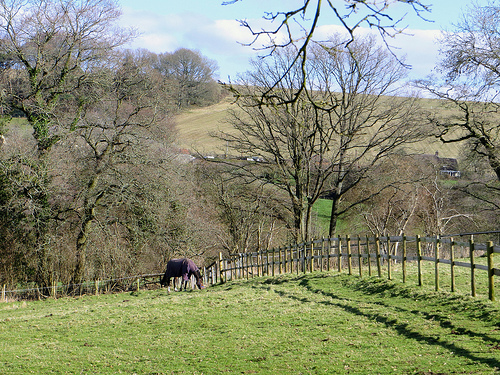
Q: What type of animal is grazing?
A: Horse.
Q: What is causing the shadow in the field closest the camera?
A: Fence.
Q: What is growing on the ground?
A: Grass.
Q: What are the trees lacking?
A: Leaves.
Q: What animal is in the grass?
A: Horse.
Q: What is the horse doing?
A: Eating.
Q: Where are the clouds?
A: In the sky.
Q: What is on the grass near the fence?
A: Shadow.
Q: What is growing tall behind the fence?
A: Trees.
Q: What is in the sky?
A: Clouds.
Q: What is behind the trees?
A: A house.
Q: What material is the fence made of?
A: Wood.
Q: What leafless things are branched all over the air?
A: Branches.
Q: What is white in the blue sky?
A: Clouds.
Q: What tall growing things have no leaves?
A: Trees.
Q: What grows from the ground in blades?
A: Grass.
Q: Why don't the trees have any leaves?
A: They fell off.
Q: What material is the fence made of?
A: Wood.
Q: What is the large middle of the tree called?
A: Trunk.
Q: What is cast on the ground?
A: Shadow.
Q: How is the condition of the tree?
A: The tree is dry.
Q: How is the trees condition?
A: The tree is branchy.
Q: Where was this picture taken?
A: On a horse farm.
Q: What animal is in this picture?
A: Horse.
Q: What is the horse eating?
A: Grass.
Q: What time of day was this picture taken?
A: Day time.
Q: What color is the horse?
A: Brown.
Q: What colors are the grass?
A: Green and yellow.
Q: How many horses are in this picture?
A: One.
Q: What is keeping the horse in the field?
A: A fence.